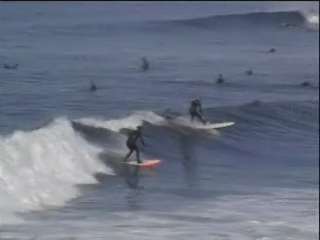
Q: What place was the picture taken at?
A: It was taken at the ocean.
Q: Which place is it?
A: It is an ocean.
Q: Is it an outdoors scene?
A: Yes, it is outdoors.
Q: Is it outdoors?
A: Yes, it is outdoors.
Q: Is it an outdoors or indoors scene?
A: It is outdoors.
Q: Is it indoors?
A: No, it is outdoors.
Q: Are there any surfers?
A: Yes, there is a surfer.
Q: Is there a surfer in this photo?
A: Yes, there is a surfer.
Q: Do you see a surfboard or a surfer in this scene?
A: Yes, there is a surfer.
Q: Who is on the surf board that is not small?
A: The surfer is on the surf board.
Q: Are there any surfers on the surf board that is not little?
A: Yes, there is a surfer on the surfboard.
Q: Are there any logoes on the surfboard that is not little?
A: No, there is a surfer on the surfboard.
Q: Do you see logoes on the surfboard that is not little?
A: No, there is a surfer on the surfboard.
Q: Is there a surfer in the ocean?
A: Yes, there is a surfer in the ocean.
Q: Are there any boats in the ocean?
A: No, there is a surfer in the ocean.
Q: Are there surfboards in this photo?
A: Yes, there is a surfboard.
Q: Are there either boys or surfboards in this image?
A: Yes, there is a surfboard.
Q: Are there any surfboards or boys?
A: Yes, there is a surfboard.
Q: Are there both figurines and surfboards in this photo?
A: No, there is a surfboard but no figurines.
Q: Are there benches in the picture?
A: No, there are no benches.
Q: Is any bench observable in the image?
A: No, there are no benches.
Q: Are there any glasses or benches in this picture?
A: No, there are no benches or glasses.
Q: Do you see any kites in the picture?
A: No, there are no kites.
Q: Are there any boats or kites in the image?
A: No, there are no kites or boats.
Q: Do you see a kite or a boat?
A: No, there are no kites or boats.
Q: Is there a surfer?
A: Yes, there is a surfer.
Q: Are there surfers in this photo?
A: Yes, there is a surfer.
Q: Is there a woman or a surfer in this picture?
A: Yes, there is a surfer.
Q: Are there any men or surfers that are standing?
A: Yes, the surfer is standing.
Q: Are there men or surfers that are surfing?
A: Yes, the surfer is surfing.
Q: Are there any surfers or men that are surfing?
A: Yes, the surfer is surfing.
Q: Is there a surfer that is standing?
A: Yes, there is a surfer that is standing.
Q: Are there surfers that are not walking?
A: Yes, there is a surfer that is standing.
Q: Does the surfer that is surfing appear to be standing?
A: Yes, the surfer is standing.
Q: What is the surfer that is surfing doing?
A: The surfer is standing.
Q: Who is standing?
A: The surfer is standing.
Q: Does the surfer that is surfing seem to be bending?
A: No, the surfer is standing.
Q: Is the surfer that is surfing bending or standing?
A: The surfer is standing.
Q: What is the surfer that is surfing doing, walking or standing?
A: The surfer is standing.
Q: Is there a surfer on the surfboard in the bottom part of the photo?
A: Yes, there is a surfer on the surfboard.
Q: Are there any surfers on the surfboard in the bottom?
A: Yes, there is a surfer on the surfboard.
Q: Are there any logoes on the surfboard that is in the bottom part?
A: No, there is a surfer on the surfboard.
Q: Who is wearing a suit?
A: The surfer is wearing a suit.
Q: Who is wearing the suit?
A: The surfer is wearing a suit.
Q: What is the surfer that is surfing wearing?
A: The surfer is wearing a suit.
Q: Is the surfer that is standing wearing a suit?
A: Yes, the surfer is wearing a suit.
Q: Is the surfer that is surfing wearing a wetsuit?
A: No, the surfer is wearing a suit.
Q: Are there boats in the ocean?
A: No, there is a surfer in the ocean.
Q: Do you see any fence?
A: No, there are no fences.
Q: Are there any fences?
A: No, there are no fences.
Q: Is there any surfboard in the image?
A: Yes, there is a surfboard.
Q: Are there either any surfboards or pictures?
A: Yes, there is a surfboard.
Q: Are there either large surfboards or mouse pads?
A: Yes, there is a large surfboard.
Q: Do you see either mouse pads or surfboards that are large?
A: Yes, the surfboard is large.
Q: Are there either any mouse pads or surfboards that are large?
A: Yes, the surfboard is large.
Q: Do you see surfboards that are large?
A: Yes, there is a large surfboard.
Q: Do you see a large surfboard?
A: Yes, there is a large surfboard.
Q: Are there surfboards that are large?
A: Yes, there is a surfboard that is large.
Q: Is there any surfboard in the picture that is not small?
A: Yes, there is a large surfboard.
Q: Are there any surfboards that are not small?
A: Yes, there is a large surfboard.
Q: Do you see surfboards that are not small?
A: Yes, there is a large surfboard.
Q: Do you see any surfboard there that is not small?
A: Yes, there is a large surfboard.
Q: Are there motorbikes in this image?
A: No, there are no motorbikes.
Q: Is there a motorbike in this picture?
A: No, there are no motorcycles.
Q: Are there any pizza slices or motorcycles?
A: No, there are no motorcycles or pizza slices.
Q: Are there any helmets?
A: No, there are no helmets.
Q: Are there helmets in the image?
A: No, there are no helmets.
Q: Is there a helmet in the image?
A: No, there are no helmets.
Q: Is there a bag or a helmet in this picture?
A: No, there are no helmets or bags.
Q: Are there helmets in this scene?
A: No, there are no helmets.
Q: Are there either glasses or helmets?
A: No, there are no helmets or glasses.